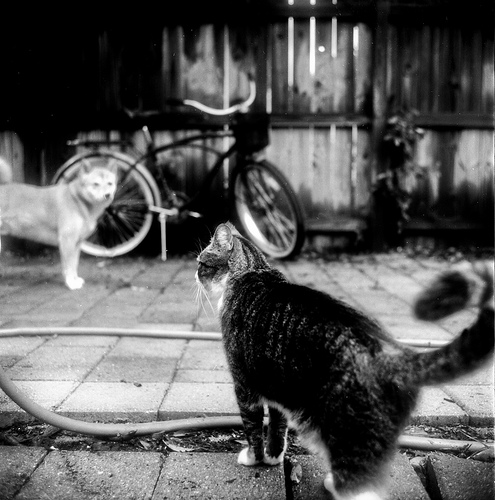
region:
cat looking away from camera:
[189, 217, 478, 479]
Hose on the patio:
[4, 311, 493, 462]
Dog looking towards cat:
[3, 147, 128, 315]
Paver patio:
[10, 248, 493, 431]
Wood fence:
[5, 5, 483, 225]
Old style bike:
[62, 75, 300, 251]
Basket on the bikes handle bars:
[218, 100, 290, 165]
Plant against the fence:
[364, 91, 434, 278]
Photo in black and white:
[13, 37, 477, 447]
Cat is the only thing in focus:
[181, 211, 460, 482]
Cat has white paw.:
[240, 437, 257, 483]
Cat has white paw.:
[250, 431, 305, 497]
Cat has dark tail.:
[418, 256, 485, 381]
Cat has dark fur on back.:
[272, 293, 356, 423]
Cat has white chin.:
[201, 268, 243, 371]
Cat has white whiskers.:
[183, 258, 230, 372]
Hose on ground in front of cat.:
[93, 388, 254, 467]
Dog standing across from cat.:
[42, 202, 160, 373]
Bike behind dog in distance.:
[218, 176, 329, 291]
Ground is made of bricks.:
[76, 292, 186, 473]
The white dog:
[0, 150, 118, 290]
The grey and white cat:
[188, 206, 492, 498]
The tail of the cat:
[407, 250, 493, 385]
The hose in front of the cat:
[0, 322, 494, 454]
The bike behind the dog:
[56, 69, 309, 267]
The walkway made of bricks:
[1, 257, 493, 498]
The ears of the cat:
[213, 217, 243, 251]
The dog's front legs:
[54, 230, 95, 288]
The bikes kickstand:
[153, 208, 174, 265]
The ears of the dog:
[71, 155, 120, 179]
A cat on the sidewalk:
[190, 217, 494, 498]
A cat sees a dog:
[2, 147, 487, 492]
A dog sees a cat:
[6, 152, 470, 466]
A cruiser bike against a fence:
[41, 73, 340, 260]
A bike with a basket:
[162, 72, 321, 219]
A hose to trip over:
[0, 225, 494, 497]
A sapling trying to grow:
[368, 111, 448, 253]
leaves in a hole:
[3, 400, 494, 474]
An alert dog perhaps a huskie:
[1, 153, 139, 290]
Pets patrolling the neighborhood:
[2, 32, 477, 490]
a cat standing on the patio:
[192, 217, 488, 482]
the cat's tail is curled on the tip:
[364, 258, 494, 387]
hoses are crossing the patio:
[5, 280, 491, 459]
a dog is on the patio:
[6, 144, 117, 298]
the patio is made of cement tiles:
[5, 248, 494, 426]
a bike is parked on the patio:
[35, 78, 312, 266]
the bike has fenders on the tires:
[44, 146, 310, 255]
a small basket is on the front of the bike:
[227, 109, 272, 156]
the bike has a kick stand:
[147, 203, 184, 270]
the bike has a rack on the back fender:
[63, 126, 135, 157]